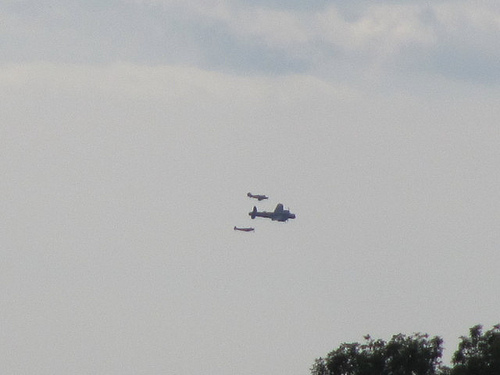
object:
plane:
[247, 192, 269, 201]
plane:
[234, 227, 254, 232]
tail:
[249, 206, 257, 218]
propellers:
[267, 196, 269, 200]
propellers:
[287, 208, 289, 221]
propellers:
[253, 228, 256, 232]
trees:
[451, 323, 498, 374]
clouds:
[0, 0, 499, 72]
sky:
[0, 0, 500, 373]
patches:
[0, 0, 500, 89]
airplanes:
[249, 203, 295, 221]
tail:
[247, 193, 252, 198]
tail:
[234, 226, 237, 229]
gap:
[440, 331, 462, 372]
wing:
[274, 203, 284, 212]